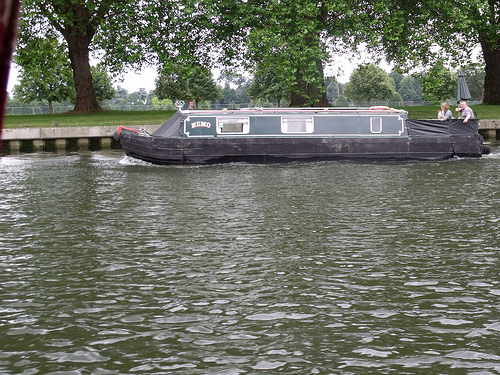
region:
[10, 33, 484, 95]
light of daytime sky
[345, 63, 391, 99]
green leaves of tree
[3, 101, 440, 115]
fence in the distance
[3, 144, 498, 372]
surface of rippled water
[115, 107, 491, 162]
flat boat on water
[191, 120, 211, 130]
curved word on boat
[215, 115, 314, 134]
two windows on boat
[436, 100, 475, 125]
people on back of boat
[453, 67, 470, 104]
closed top of umbrella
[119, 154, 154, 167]
splashed water in front of boat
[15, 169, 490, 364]
body of water in park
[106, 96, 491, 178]
boat in the water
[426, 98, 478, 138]
people on the boat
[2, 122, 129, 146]
walled structure near water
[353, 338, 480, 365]
ripples in the water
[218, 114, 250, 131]
window on the boat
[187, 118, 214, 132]
lettering on the boat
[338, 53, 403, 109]
tree in the park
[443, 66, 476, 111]
tent in the park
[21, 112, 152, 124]
grass in the park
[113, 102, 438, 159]
this is a boat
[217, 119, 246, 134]
this is the window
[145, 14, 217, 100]
this is a tree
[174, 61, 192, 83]
the leaves are green in color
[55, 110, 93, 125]
this is a grass area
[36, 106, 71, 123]
the grass is green in color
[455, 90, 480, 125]
this is a man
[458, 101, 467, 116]
the man is light skinned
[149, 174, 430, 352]
this is a water body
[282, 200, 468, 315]
the water is calm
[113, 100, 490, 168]
a long black boat that people are riding on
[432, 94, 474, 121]
people sitting in the back of the long boat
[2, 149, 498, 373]
the water the boat is riding on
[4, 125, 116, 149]
the wall next to the boat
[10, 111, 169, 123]
some of the green grass in the park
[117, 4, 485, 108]
a bunch of green leaves hanging from the tree branches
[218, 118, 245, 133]
a window on the side of the bus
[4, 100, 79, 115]
a fence behind the trees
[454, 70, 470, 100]
a grey umbrella sitting on the boat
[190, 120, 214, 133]
a name written on the bus